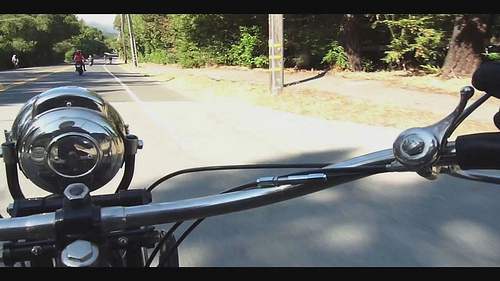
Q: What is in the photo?
A: Motorcycle.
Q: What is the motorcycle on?
A: Street.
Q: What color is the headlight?
A: Silver.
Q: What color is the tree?
A: Green.